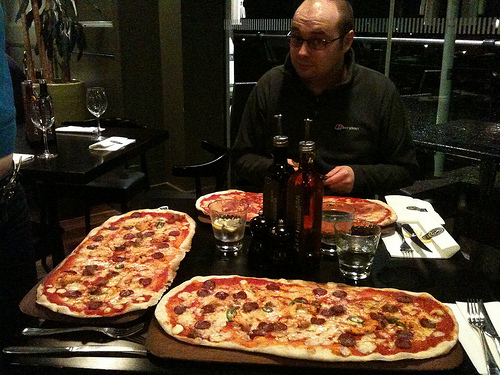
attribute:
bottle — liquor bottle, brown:
[284, 114, 325, 267]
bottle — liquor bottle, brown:
[258, 111, 296, 237]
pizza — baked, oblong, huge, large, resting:
[192, 185, 400, 237]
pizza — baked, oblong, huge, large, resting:
[32, 203, 201, 322]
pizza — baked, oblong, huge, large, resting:
[147, 271, 463, 368]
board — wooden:
[195, 206, 398, 240]